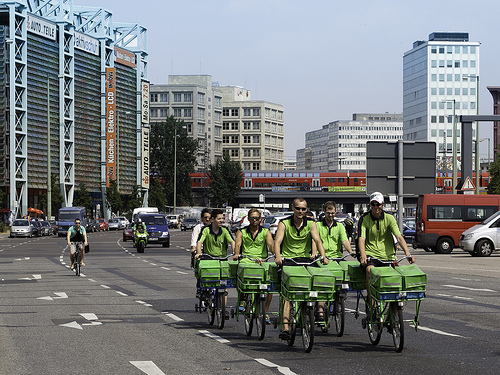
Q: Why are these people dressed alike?
A: They belong to an organized group.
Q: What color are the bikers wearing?
A: Lime green.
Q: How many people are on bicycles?
A: Seven.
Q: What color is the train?
A: Red.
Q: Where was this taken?
A: Downtown.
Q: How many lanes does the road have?
A: Four.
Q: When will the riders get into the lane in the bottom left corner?
A: When they need to turn right.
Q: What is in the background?
A: Office buildings.